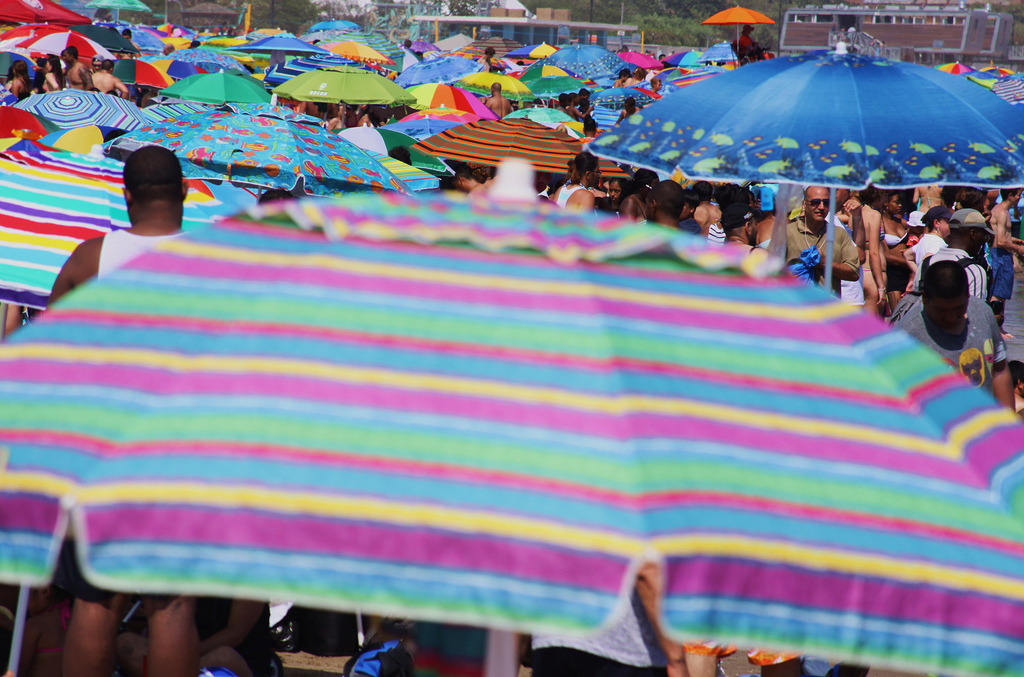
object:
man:
[43, 144, 191, 306]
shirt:
[98, 228, 181, 282]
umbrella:
[0, 26, 113, 65]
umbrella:
[3, 22, 57, 59]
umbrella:
[96, 101, 416, 196]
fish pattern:
[325, 152, 352, 164]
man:
[922, 208, 996, 299]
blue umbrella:
[589, 42, 1019, 191]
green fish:
[837, 140, 880, 157]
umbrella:
[400, 81, 498, 118]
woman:
[871, 190, 914, 321]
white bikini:
[884, 230, 911, 247]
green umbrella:
[269, 71, 416, 106]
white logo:
[309, 82, 329, 96]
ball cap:
[948, 209, 995, 236]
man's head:
[939, 207, 999, 251]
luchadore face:
[956, 348, 984, 389]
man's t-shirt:
[884, 293, 1008, 397]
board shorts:
[988, 236, 1015, 303]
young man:
[983, 174, 1021, 338]